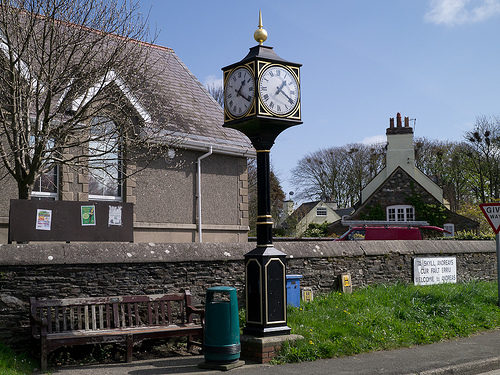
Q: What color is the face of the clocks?
A: White.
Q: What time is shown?
A: 1:21.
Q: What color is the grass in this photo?
A: Green.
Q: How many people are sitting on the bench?
A: Zero.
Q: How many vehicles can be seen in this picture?
A: One.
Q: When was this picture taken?
A: Daytime.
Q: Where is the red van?
A: Behind the wall.